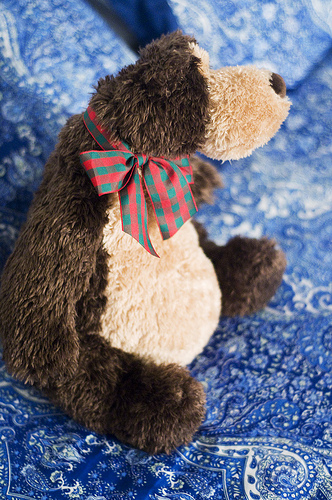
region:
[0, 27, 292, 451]
brown and tan teddy bear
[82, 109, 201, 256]
a green and red bow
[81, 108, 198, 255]
bow around a teddy bears neck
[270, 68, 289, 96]
a bear's nose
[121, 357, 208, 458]
a teddy bear's right foot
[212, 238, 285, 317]
a teddy bear's left foot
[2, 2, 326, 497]
teddy bear sitting on a blue bedspread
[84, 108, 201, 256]
ribbon tied around a teddy bear's neck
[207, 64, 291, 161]
a teddy bear's snout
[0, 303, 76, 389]
a teddy bear's right paw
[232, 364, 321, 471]
blue cloth bear is on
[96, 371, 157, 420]
brown fur of stuffed bear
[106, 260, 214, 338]
beige fur of stuffed bear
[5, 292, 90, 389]
right arm of bear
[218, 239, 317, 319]
left foot of bear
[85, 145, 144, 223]
red and green bowtie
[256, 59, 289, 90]
brown nose of bear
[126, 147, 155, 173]
knot of a bowtie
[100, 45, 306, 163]
head of a stuffed bear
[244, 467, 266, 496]
white design on cloth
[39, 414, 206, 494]
Stuffed animal sitting on blue blanket.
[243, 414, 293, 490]
Blue paisley printed blanket.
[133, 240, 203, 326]
Tan tummy on animal.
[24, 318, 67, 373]
Dark brown paw on animal.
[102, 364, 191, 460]
Animal has brown leg.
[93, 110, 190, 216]
Green and red bow on animal.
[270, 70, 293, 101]
Animal has brown nose.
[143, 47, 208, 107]
Animal has brown ear.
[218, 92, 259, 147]
Animal has tan face.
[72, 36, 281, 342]
Stuffed animal is a bear.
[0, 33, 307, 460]
Brown and cream stuffed animal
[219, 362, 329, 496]
Blue and white blanket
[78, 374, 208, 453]
Brown fur on a stuffed toy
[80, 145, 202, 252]
Red and green plaid bow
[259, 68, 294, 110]
Brown nose on a stuffed toy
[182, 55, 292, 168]
Cream color snout on a stuffed animal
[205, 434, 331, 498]
White design on blue cloth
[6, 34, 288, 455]
A toy bear with a bow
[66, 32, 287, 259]
Bow around the neck of a stuffed bear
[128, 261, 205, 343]
Cream fake fur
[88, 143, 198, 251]
The bow around the stuff animal's neck.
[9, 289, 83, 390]
The left arm of the stuffed animal.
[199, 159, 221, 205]
The right arm of the stuffed animal.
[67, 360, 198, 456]
The left leg of the stuffed animal.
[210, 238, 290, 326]
The right leg of the stuffed animal.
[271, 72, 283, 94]
The brown nose of the stuffed animal.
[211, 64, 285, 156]
The beige fur near the stuffed animal's nose.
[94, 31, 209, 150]
The brown fur on the stuffed animal's head.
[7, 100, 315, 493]
The blue bandana the stuffed animal is sitting on.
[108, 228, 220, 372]
The beige area of the stomach on the stuffed animal.